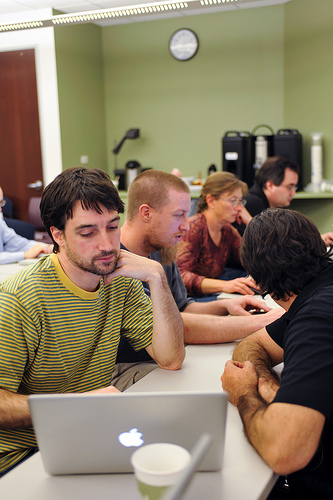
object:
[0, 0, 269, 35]
lighting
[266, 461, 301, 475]
elbow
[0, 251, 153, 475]
shirt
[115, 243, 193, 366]
shirt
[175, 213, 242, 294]
shirt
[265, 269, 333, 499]
shirt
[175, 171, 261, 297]
woman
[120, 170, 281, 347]
man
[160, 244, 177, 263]
beard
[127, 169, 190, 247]
head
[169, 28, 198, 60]
clock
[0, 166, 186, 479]
man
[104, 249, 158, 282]
hand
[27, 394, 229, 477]
computer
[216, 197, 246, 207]
glasses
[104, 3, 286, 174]
wall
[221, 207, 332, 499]
man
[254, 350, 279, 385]
hair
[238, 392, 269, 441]
hair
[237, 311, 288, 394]
arm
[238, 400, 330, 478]
arm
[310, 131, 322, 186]
cups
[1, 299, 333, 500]
table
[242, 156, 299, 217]
man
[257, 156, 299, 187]
hair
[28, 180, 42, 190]
handle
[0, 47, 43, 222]
door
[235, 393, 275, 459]
forearm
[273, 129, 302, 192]
coffee dispenser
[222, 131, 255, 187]
coffee dispenser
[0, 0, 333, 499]
classroom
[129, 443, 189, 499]
cup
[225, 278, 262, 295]
hand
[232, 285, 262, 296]
mouse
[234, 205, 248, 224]
hand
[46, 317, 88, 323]
stripes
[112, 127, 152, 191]
projector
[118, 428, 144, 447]
label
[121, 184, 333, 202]
counter